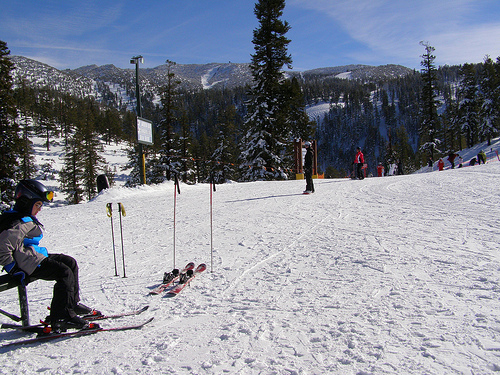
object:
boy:
[0, 179, 105, 335]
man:
[301, 140, 316, 194]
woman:
[352, 146, 367, 181]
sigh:
[133, 116, 157, 147]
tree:
[244, 0, 298, 179]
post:
[129, 53, 148, 185]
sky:
[0, 1, 251, 56]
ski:
[161, 262, 207, 301]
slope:
[406, 128, 500, 203]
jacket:
[353, 152, 365, 167]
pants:
[33, 249, 97, 321]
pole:
[207, 168, 217, 283]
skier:
[388, 159, 399, 177]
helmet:
[13, 178, 55, 218]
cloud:
[439, 14, 499, 47]